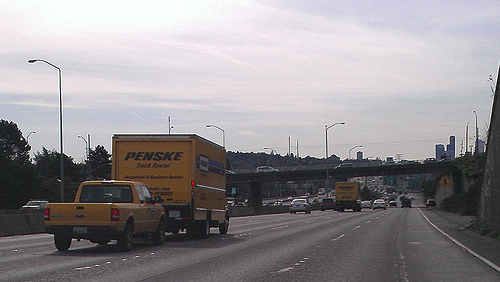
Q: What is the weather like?
A: It is cloudy.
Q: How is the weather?
A: It is cloudy.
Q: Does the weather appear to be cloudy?
A: Yes, it is cloudy.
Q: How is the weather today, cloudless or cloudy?
A: It is cloudy.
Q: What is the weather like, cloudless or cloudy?
A: It is cloudy.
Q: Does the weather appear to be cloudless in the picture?
A: No, it is cloudy.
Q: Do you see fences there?
A: No, there are no fences.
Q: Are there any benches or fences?
A: No, there are no fences or benches.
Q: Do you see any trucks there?
A: Yes, there is a truck.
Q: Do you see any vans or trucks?
A: Yes, there is a truck.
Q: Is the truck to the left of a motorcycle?
A: No, the truck is to the left of the car.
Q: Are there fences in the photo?
A: No, there are no fences.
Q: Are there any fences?
A: No, there are no fences.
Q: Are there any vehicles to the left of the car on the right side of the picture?
A: Yes, there are vehicles to the left of the car.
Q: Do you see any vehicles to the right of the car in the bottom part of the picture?
A: No, the vehicles are to the left of the car.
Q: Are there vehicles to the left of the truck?
A: No, the vehicles are to the right of the truck.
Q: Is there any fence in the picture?
A: No, there are no fences.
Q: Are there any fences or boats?
A: No, there are no fences or boats.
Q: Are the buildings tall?
A: Yes, the buildings are tall.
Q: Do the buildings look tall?
A: Yes, the buildings are tall.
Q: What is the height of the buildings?
A: The buildings are tall.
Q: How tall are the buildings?
A: The buildings are tall.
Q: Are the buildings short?
A: No, the buildings are tall.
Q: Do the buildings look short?
A: No, the buildings are tall.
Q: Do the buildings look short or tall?
A: The buildings are tall.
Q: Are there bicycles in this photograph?
A: No, there are no bicycles.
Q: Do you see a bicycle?
A: No, there are no bicycles.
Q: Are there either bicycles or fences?
A: No, there are no bicycles or fences.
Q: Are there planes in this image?
A: No, there are no planes.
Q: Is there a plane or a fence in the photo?
A: No, there are no airplanes or fences.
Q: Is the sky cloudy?
A: Yes, the sky is cloudy.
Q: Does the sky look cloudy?
A: Yes, the sky is cloudy.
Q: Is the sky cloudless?
A: No, the sky is cloudy.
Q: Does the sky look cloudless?
A: No, the sky is cloudy.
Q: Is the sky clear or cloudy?
A: The sky is cloudy.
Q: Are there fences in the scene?
A: No, there are no fences.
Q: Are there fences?
A: No, there are no fences.